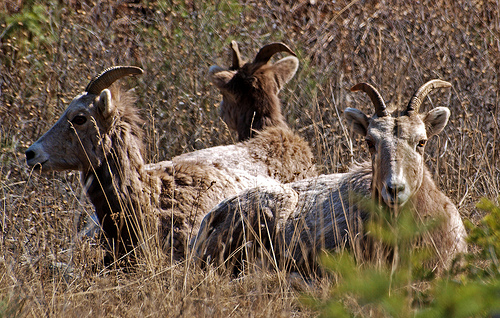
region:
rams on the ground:
[13, 10, 484, 291]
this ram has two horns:
[333, 65, 463, 205]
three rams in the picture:
[21, 30, 466, 265]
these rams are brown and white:
[25, 26, 468, 277]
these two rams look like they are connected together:
[20, 18, 302, 200]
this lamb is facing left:
[8, 61, 158, 183]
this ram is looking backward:
[173, 16, 309, 119]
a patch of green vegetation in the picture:
[311, 216, 497, 306]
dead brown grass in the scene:
[21, 226, 233, 311]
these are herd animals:
[9, 13, 484, 297]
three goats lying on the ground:
[14, 20, 476, 304]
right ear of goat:
[422, 103, 454, 145]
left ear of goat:
[342, 100, 372, 135]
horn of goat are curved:
[346, 60, 456, 125]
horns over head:
[206, 30, 302, 110]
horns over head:
[71, 45, 153, 110]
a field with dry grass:
[7, 3, 490, 309]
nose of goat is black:
[384, 174, 405, 196]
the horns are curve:
[81, 55, 145, 100]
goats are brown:
[19, 22, 479, 308]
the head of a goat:
[359, 77, 474, 214]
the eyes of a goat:
[359, 126, 451, 168]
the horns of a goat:
[350, 56, 474, 133]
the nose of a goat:
[368, 171, 424, 208]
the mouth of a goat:
[376, 169, 430, 211]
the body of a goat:
[84, 91, 339, 282]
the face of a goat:
[354, 105, 449, 220]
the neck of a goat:
[231, 96, 309, 151]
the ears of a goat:
[338, 71, 459, 136]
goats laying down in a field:
[46, 20, 471, 282]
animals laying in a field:
[30, 45, 465, 277]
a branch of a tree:
[318, 213, 487, 316]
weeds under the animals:
[62, 225, 264, 296]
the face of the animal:
[341, 78, 447, 198]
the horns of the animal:
[345, 67, 441, 113]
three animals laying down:
[33, 34, 458, 275]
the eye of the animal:
[416, 138, 428, 148]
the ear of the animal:
[424, 106, 449, 135]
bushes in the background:
[23, 18, 182, 60]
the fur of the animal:
[201, 139, 306, 176]